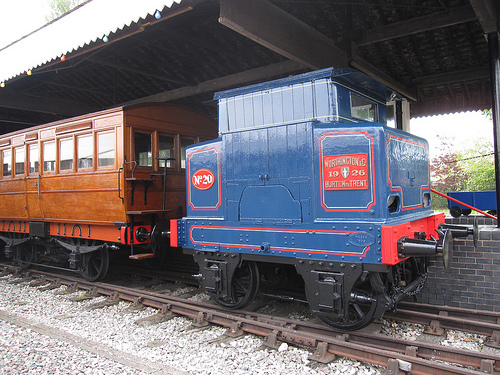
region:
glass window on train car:
[96, 133, 116, 168]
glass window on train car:
[77, 133, 95, 169]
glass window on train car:
[58, 138, 75, 170]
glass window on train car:
[41, 141, 57, 171]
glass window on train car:
[13, 147, 26, 174]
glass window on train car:
[2, 149, 12, 175]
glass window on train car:
[133, 132, 151, 168]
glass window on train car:
[159, 133, 174, 170]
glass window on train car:
[181, 137, 196, 171]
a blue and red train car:
[167, 65, 497, 333]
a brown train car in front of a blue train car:
[2, 99, 217, 284]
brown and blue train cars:
[2, 63, 479, 328]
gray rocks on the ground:
[5, 316, 127, 373]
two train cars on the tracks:
[0, 64, 497, 372]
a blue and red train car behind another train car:
[167, 65, 496, 333]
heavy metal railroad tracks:
[410, 300, 499, 374]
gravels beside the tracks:
[0, 266, 196, 335]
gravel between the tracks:
[441, 326, 481, 347]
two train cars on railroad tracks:
[1, 66, 497, 371]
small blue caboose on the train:
[169, 69, 469, 329]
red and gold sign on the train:
[320, 152, 369, 194]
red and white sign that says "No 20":
[190, 169, 215, 191]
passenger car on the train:
[0, 104, 214, 285]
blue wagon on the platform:
[447, 187, 497, 214]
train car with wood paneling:
[0, 103, 217, 271]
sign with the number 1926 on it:
[320, 152, 370, 193]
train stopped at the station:
[0, 63, 465, 332]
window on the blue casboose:
[348, 90, 381, 125]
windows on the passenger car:
[0, 134, 205, 176]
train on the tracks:
[1, 53, 471, 350]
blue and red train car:
[153, 61, 471, 341]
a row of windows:
[2, 119, 122, 186]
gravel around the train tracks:
[1, 249, 498, 374]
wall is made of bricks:
[388, 230, 498, 314]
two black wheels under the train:
[186, 245, 397, 336]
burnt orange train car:
[1, 101, 183, 290]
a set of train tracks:
[0, 250, 495, 374]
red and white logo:
[187, 165, 214, 190]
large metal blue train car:
[172, 64, 482, 335]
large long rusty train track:
[0, 261, 499, 373]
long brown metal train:
[0, 102, 219, 278]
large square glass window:
[91, 128, 118, 168]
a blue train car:
[165, 60, 483, 335]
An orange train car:
[3, 92, 218, 283]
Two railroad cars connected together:
[0, 58, 486, 334]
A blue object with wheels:
[445, 185, 496, 215]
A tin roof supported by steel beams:
[0, 0, 499, 118]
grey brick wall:
[405, 220, 497, 312]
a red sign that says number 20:
[187, 163, 218, 195]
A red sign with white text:
[313, 149, 378, 197]